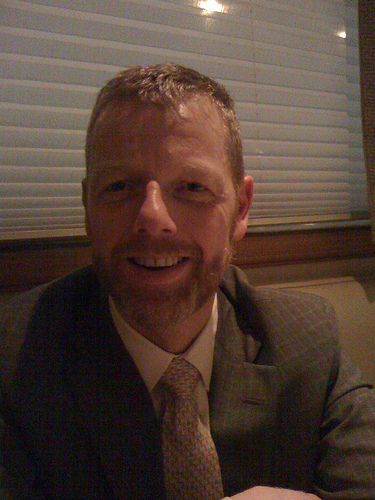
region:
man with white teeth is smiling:
[84, 236, 244, 300]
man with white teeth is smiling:
[77, 233, 224, 291]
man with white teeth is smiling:
[109, 244, 197, 287]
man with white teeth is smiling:
[102, 223, 273, 279]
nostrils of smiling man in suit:
[127, 214, 178, 238]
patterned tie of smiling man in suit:
[153, 354, 221, 499]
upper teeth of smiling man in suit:
[114, 245, 191, 284]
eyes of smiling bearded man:
[94, 175, 218, 199]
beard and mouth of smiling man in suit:
[90, 234, 228, 331]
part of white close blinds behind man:
[275, 100, 362, 218]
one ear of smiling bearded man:
[232, 171, 256, 246]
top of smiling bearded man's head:
[90, 60, 236, 122]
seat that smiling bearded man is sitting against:
[338, 274, 370, 326]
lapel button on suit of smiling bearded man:
[234, 357, 285, 434]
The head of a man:
[73, 55, 259, 336]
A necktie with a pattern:
[151, 353, 225, 498]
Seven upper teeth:
[131, 254, 186, 267]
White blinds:
[256, 12, 356, 221]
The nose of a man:
[134, 175, 184, 246]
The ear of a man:
[232, 172, 256, 248]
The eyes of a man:
[95, 173, 215, 205]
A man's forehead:
[102, 108, 218, 165]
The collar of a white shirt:
[178, 313, 220, 393]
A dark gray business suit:
[206, 267, 353, 495]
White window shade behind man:
[0, 1, 373, 228]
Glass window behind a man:
[2, 4, 372, 242]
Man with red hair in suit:
[2, 61, 374, 497]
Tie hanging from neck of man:
[153, 351, 232, 498]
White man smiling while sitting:
[0, 64, 374, 498]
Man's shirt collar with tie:
[104, 301, 237, 393]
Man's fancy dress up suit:
[4, 266, 372, 496]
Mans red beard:
[88, 239, 234, 335]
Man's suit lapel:
[61, 272, 292, 497]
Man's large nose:
[130, 176, 178, 248]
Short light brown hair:
[89, 59, 210, 110]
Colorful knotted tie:
[143, 342, 230, 493]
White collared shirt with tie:
[106, 303, 250, 492]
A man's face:
[77, 94, 245, 323]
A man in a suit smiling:
[36, 61, 272, 397]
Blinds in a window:
[249, 28, 347, 239]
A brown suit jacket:
[207, 270, 350, 498]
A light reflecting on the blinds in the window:
[180, 1, 253, 35]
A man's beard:
[94, 261, 244, 333]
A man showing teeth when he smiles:
[87, 114, 239, 322]